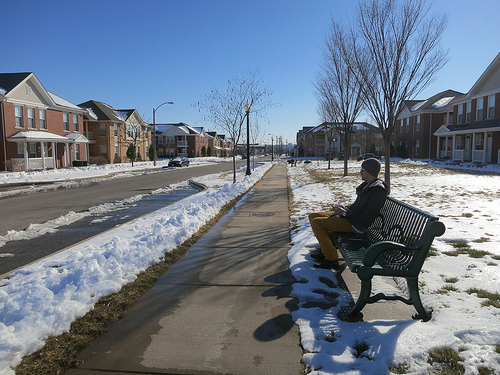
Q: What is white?
A: Snow.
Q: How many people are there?
A: One.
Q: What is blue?
A: Sky.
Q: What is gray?
A: Road.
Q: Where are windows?
A: On houses.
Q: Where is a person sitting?
A: On a bench.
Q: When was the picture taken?
A: Daytime.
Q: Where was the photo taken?
A: In a neighborhood.